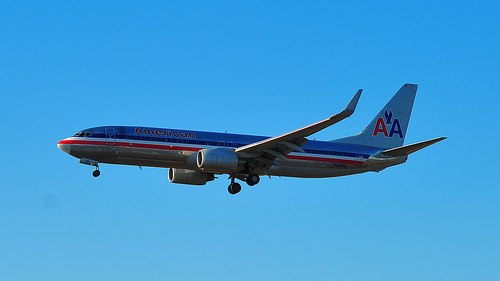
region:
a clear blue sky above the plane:
[2, 1, 496, 276]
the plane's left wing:
[235, 85, 360, 160]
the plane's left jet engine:
[195, 150, 242, 171]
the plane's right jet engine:
[167, 168, 212, 184]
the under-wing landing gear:
[225, 166, 262, 191]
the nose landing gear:
[87, 161, 98, 174]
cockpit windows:
[75, 130, 92, 135]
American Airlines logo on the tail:
[374, 108, 401, 137]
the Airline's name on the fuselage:
[134, 126, 197, 139]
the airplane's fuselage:
[57, 125, 407, 174]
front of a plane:
[37, 112, 129, 174]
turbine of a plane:
[146, 154, 218, 193]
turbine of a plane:
[191, 143, 246, 173]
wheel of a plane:
[89, 167, 106, 177]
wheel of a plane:
[222, 178, 249, 203]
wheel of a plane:
[242, 165, 267, 190]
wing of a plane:
[267, 75, 378, 167]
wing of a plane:
[377, 129, 460, 166]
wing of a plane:
[354, 38, 434, 143]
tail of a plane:
[313, 54, 461, 184]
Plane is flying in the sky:
[51, 35, 477, 278]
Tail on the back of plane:
[369, 64, 454, 214]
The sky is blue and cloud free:
[325, 161, 465, 276]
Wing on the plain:
[262, 73, 365, 180]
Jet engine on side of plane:
[190, 130, 249, 192]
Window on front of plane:
[60, 124, 104, 144]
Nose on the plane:
[51, 129, 81, 158]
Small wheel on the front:
[81, 165, 117, 194]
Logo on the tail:
[369, 98, 403, 141]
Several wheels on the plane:
[216, 165, 276, 205]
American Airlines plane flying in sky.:
[56, 83, 448, 195]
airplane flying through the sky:
[12, 11, 474, 251]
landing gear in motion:
[222, 170, 258, 195]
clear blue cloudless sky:
[15, 10, 257, 101]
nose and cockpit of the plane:
[50, 120, 95, 155]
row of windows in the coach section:
[306, 145, 352, 155]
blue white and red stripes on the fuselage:
[115, 130, 136, 145]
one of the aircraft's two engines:
[192, 145, 237, 172]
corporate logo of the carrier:
[367, 106, 403, 138]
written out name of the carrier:
[130, 122, 195, 142]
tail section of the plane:
[367, 73, 449, 186]